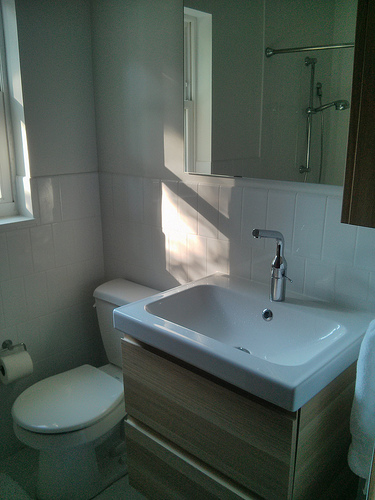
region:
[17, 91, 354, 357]
a sink in a bathroom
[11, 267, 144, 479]
a toilet in the corner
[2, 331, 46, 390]
a roll of toilet paper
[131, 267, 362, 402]
a sink in the bathroom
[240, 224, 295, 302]
a faucet on the sink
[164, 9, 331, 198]
a mirror on the wall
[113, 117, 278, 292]
light shining in the bathroom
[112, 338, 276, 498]
bathroom cabinet under the sink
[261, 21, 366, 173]
the reflection of the shower in the mirror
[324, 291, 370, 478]
a towel on the side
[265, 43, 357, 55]
A silver shower curtain rod.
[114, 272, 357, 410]
A white bathroom sink.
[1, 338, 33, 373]
A silver toilet paper holder.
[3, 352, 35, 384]
A white roll of toilet paper.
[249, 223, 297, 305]
Silver bathroom sink fixtures.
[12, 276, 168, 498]
A white toilet.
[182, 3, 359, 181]
A mirror on the wall.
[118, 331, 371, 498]
Wooden drawers under the sink.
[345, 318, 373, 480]
A white towel.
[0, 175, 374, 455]
White tiles on the walls.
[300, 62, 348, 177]
shower head on the bar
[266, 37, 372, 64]
shower curtain rod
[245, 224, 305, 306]
faucet to the sink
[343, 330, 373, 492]
towel next to the sink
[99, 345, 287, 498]
drawers on the cabinet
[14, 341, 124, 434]
toilet seat is down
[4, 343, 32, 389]
toilet paper on the holder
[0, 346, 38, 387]
toilet paper roll is white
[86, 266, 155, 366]
tank on the toilet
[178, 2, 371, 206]
mirror above the sink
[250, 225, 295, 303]
a chrome bathroom faucet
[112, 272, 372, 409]
a white porcelain bathroom sink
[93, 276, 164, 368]
a white porcelain toilet tank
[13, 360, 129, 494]
a white porcelain toilet bowl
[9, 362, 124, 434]
a white toilet seat lid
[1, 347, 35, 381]
a white toilet paper roll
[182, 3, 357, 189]
a wall mounted vanity mirror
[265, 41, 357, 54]
reflection of a shower rod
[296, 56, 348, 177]
reflection of a shower head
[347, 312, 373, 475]
a hanging white towel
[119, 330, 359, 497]
wooden drawers under sink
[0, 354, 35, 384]
roll of toilet paper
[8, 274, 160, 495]
white toilet beside sink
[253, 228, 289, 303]
faucet nozzle is metal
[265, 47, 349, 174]
shower rod and shower head seen in mirror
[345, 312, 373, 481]
white towel beside sink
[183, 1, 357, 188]
large square mirror above sink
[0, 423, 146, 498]
floor is cream tile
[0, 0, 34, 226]
window sill above toilet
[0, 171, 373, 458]
white tile running along wall